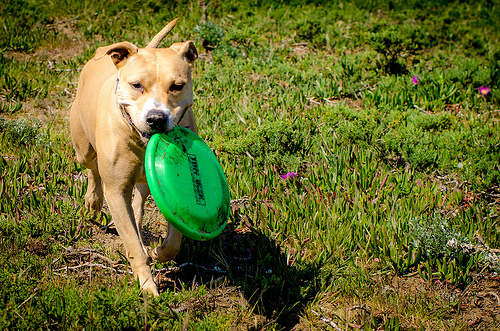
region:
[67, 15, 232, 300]
A dog carrying a green frisbee.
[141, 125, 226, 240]
The green frisbee in the dog's mouth.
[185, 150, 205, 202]
Black printing on the frisbee.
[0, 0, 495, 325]
The field the dog is in.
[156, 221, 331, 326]
The dog's shadow on the ground.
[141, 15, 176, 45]
Top of the dog's brown tail.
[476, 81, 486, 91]
A pink and yellow flower in the field.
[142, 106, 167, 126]
The nose of the dog.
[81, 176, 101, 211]
One of the dog's back paws.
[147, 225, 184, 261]
Dog's front paw nearest the frisbee.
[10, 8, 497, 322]
a scene outside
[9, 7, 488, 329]
a scene during the day time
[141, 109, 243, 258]
a green disc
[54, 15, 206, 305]
a tan dog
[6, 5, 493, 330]
a green lawn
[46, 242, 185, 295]
a wood twig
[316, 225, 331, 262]
a blade of grass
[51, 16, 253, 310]
dog and his toy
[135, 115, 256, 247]
a green frisbee in the dog's mouth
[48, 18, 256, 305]
a tan colored dog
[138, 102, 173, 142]
nose of the dog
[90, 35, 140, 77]
flopped ear on the dog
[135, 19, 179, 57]
tail of the dog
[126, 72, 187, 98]
eyes on the dog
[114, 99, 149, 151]
mouth of the dog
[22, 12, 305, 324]
a dog walking in grass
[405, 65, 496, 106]
purple flowers in the grass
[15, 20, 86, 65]
a brown patch in the grass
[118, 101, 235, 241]
green frisbee in dog's mouth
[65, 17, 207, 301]
dog holding green frisbee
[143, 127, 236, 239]
black writing on frisbee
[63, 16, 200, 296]
dog has a black nose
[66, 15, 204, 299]
dog is light brown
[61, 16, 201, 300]
dog has front legs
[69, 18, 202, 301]
dog has light brown tail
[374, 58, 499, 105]
purple flower in grass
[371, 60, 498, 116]
purple flower in grass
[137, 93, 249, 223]
a green frisbee in the mouth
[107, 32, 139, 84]
an ear on the dog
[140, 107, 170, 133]
a nose on the dog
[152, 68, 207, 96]
an eye on the dog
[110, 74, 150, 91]
an eye on the dog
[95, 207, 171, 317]
a leg on the dog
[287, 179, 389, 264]
grass around the dog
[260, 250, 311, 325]
grass around the dog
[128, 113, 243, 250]
green frisbee in dog mouth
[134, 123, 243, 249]
green frisbee in dog mouth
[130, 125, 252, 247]
green frisbee in dog mouth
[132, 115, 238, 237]
green frisbee in dog mouth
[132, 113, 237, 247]
green frisbee in dog mouth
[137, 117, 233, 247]
green frisbee in dog mouth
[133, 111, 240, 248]
A round green frisbee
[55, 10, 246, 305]
A dog holding a frisbee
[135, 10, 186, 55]
Tail of a dog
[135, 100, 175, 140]
Black nose of a dog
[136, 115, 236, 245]
The frisbee is dirty